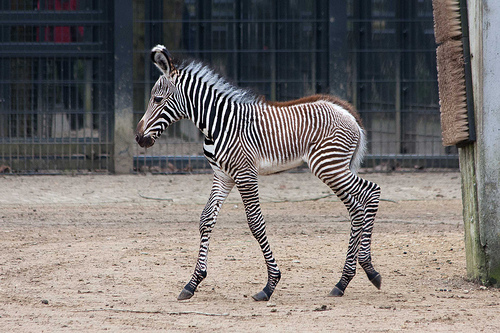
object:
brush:
[430, 1, 470, 147]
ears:
[148, 45, 171, 79]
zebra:
[135, 45, 380, 300]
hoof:
[176, 290, 194, 300]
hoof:
[252, 290, 269, 302]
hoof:
[370, 273, 382, 289]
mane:
[183, 59, 260, 103]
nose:
[133, 135, 141, 142]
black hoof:
[327, 287, 344, 297]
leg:
[232, 172, 281, 288]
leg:
[304, 157, 381, 273]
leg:
[323, 180, 364, 283]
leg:
[186, 178, 236, 286]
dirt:
[0, 290, 90, 330]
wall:
[465, 0, 498, 287]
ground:
[54, 214, 165, 271]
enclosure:
[0, 0, 500, 333]